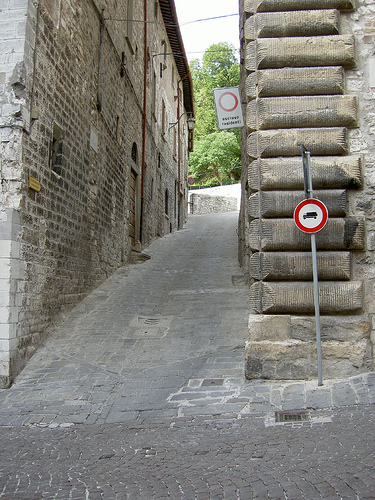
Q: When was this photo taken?
A: Day time.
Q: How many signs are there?
A: Three.